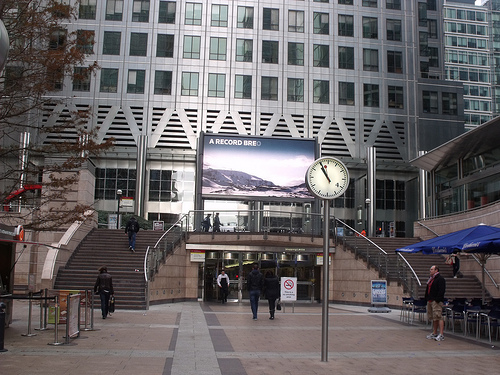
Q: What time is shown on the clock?
A: 10:55.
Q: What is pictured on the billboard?
A: Mountains.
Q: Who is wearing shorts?
A: The man standing on the right.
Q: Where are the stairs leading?
A: To the building's second story entrance.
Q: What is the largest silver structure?
A: A building.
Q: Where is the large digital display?
A: In front of the building.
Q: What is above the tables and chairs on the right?
A: Umbrellas.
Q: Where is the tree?
A: On the left.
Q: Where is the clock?
A: In the middle of the sidewalk.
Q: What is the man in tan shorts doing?
A: Standing by the tables and umbrellas.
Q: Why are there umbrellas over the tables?
A: To protect people from sun and rain.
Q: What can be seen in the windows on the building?
A: Reflection of another building.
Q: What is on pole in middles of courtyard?
A: Clock.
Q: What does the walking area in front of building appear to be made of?
A: Cement tiles.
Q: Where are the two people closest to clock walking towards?
A: Doors.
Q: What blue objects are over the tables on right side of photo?
A: Umbrellas.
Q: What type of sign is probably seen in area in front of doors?
A: No smoking.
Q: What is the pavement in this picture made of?
A: Brick.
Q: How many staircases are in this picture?
A: Two.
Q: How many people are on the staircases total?
A: Three.